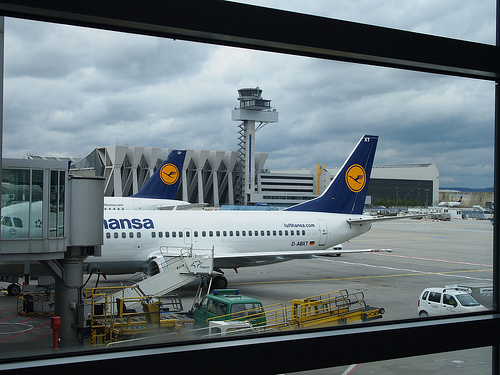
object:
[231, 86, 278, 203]
tower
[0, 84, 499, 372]
airport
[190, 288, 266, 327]
luggage truck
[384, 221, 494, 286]
tarmac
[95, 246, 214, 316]
jetway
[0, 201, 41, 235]
cockpit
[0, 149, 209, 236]
airplane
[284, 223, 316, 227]
website address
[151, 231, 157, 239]
window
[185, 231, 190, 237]
window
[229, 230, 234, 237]
window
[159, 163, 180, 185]
logo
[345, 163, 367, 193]
logo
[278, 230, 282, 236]
window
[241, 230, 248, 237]
window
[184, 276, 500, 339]
parking lot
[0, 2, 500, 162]
clouds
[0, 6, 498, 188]
sky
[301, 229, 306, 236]
window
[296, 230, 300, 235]
window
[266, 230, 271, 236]
window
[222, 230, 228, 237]
window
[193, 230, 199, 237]
window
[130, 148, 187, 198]
tail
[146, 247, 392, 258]
wing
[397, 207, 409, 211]
vehicles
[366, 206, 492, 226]
parking lot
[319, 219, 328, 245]
door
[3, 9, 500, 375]
view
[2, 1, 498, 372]
window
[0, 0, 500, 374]
day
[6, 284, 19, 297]
wheels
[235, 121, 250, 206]
stairwell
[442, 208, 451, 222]
cones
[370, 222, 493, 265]
ground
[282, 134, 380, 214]
tail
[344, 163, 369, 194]
circle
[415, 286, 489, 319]
car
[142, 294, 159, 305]
loader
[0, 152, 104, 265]
bridge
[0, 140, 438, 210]
airport terminal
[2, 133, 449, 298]
airliner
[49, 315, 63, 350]
meter